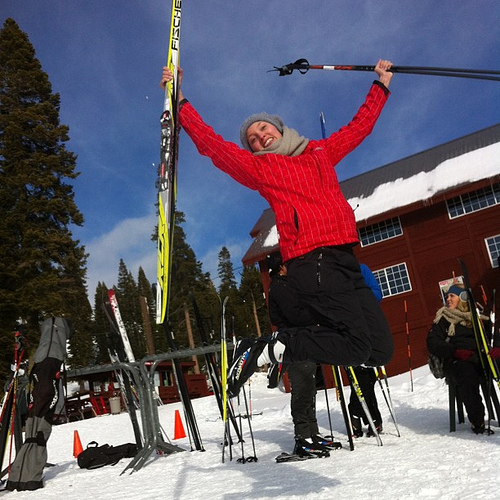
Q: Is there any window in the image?
A: Yes, there is a window.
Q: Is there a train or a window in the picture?
A: Yes, there is a window.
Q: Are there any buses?
A: No, there are no buses.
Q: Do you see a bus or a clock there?
A: No, there are no buses or clocks.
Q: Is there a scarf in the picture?
A: Yes, there is a scarf.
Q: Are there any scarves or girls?
A: Yes, there is a scarf.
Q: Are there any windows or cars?
A: Yes, there is a window.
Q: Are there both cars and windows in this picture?
A: No, there is a window but no cars.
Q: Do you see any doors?
A: No, there are no doors.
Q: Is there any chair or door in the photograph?
A: No, there are no doors or chairs.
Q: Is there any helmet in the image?
A: No, there are no helmets.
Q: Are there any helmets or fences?
A: No, there are no helmets or fences.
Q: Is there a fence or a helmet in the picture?
A: No, there are no helmets or fences.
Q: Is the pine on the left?
A: Yes, the pine is on the left of the image.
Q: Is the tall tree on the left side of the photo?
A: Yes, the pine is on the left of the image.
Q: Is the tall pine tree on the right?
A: No, the pine tree is on the left of the image.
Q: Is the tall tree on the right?
A: No, the pine tree is on the left of the image.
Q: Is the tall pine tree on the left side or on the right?
A: The pine is on the left of the image.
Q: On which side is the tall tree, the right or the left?
A: The pine is on the left of the image.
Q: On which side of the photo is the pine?
A: The pine is on the left of the image.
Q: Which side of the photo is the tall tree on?
A: The pine is on the left of the image.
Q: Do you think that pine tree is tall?
A: Yes, the pine tree is tall.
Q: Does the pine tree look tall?
A: Yes, the pine tree is tall.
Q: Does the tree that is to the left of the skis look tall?
A: Yes, the pine tree is tall.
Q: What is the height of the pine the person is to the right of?
A: The pine is tall.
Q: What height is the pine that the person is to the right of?
A: The pine is tall.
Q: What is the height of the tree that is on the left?
A: The pine is tall.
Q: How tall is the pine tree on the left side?
A: The pine tree is tall.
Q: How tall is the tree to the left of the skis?
A: The pine tree is tall.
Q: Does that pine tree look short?
A: No, the pine tree is tall.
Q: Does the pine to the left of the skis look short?
A: No, the pine is tall.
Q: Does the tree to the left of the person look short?
A: No, the pine is tall.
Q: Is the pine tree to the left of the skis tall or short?
A: The pine tree is tall.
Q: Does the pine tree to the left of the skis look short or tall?
A: The pine tree is tall.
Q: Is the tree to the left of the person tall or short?
A: The pine tree is tall.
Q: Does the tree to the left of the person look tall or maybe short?
A: The pine tree is tall.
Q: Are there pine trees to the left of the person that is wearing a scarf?
A: Yes, there is a pine tree to the left of the person.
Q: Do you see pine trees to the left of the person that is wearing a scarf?
A: Yes, there is a pine tree to the left of the person.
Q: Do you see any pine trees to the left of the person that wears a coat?
A: Yes, there is a pine tree to the left of the person.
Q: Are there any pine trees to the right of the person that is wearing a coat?
A: No, the pine tree is to the left of the person.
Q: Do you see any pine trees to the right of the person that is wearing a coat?
A: No, the pine tree is to the left of the person.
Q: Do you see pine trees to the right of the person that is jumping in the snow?
A: No, the pine tree is to the left of the person.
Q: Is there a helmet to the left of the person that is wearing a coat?
A: No, there is a pine tree to the left of the person.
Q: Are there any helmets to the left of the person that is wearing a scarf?
A: No, there is a pine tree to the left of the person.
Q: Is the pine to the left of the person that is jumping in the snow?
A: Yes, the pine is to the left of the person.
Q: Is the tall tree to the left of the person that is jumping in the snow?
A: Yes, the pine is to the left of the person.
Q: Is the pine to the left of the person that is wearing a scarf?
A: Yes, the pine is to the left of the person.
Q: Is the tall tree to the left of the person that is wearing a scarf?
A: Yes, the pine is to the left of the person.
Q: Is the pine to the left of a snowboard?
A: No, the pine is to the left of the person.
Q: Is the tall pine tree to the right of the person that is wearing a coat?
A: No, the pine tree is to the left of the person.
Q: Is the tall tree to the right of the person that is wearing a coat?
A: No, the pine tree is to the left of the person.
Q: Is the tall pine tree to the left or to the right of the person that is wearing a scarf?
A: The pine tree is to the left of the person.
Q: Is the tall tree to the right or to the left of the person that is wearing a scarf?
A: The pine tree is to the left of the person.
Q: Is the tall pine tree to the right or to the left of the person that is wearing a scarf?
A: The pine tree is to the left of the person.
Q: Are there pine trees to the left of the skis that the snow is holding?
A: Yes, there is a pine tree to the left of the skis.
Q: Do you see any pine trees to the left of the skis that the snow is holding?
A: Yes, there is a pine tree to the left of the skis.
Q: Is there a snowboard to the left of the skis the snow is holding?
A: No, there is a pine tree to the left of the skis.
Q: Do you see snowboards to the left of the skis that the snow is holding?
A: No, there is a pine tree to the left of the skis.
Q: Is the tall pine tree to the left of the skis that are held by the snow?
A: Yes, the pine tree is to the left of the skis.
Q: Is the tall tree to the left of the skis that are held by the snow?
A: Yes, the pine tree is to the left of the skis.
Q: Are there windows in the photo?
A: Yes, there is a window.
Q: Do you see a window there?
A: Yes, there is a window.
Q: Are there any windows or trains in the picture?
A: Yes, there is a window.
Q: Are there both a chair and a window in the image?
A: No, there is a window but no chairs.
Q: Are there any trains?
A: No, there are no trains.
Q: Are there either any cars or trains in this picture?
A: No, there are no trains or cars.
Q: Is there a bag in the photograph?
A: Yes, there is a bag.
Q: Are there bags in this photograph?
A: Yes, there is a bag.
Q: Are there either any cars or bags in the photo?
A: Yes, there is a bag.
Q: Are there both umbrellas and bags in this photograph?
A: No, there is a bag but no umbrellas.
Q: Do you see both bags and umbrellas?
A: No, there is a bag but no umbrellas.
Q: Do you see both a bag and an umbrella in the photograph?
A: No, there is a bag but no umbrellas.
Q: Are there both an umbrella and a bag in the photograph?
A: No, there is a bag but no umbrellas.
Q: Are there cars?
A: No, there are no cars.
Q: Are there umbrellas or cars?
A: No, there are no cars or umbrellas.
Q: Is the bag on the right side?
A: No, the bag is on the left of the image.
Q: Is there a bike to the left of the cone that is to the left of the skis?
A: No, there is a bag to the left of the safety cone.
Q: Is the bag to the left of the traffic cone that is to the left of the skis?
A: Yes, the bag is to the left of the traffic cone.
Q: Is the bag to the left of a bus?
A: No, the bag is to the left of the traffic cone.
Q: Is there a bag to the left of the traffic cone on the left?
A: Yes, there is a bag to the left of the safety cone.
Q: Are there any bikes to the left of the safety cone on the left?
A: No, there is a bag to the left of the safety cone.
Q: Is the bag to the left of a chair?
A: No, the bag is to the left of the cone.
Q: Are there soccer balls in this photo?
A: No, there are no soccer balls.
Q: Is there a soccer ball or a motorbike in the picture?
A: No, there are no soccer balls or motorcycles.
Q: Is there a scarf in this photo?
A: Yes, there is a scarf.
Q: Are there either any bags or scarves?
A: Yes, there is a scarf.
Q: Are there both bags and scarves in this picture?
A: Yes, there are both a scarf and a bag.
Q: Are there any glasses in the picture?
A: No, there are no glasses.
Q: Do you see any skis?
A: Yes, there are skis.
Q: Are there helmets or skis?
A: Yes, there are skis.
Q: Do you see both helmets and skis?
A: No, there are skis but no helmets.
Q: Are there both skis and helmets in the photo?
A: No, there are skis but no helmets.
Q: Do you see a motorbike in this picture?
A: No, there are no motorcycles.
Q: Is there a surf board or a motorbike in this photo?
A: No, there are no motorcycles or surfboards.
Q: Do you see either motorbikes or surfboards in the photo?
A: No, there are no motorbikes or surfboards.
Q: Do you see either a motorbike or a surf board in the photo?
A: No, there are no motorcycles or surfboards.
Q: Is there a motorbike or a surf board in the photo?
A: No, there are no motorcycles or surfboards.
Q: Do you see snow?
A: Yes, there is snow.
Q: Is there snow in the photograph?
A: Yes, there is snow.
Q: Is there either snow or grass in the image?
A: Yes, there is snow.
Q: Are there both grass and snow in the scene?
A: No, there is snow but no grass.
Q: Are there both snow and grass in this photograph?
A: No, there is snow but no grass.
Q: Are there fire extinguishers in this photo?
A: No, there are no fire extinguishers.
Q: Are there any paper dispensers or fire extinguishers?
A: No, there are no fire extinguishers or paper dispensers.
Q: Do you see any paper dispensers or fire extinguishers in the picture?
A: No, there are no fire extinguishers or paper dispensers.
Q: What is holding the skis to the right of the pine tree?
A: The snow is holding the skis.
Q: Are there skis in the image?
A: Yes, there are skis.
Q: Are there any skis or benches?
A: Yes, there are skis.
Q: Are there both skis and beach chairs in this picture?
A: No, there are skis but no beach chairs.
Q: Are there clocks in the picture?
A: No, there are no clocks.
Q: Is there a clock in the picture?
A: No, there are no clocks.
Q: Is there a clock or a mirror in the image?
A: No, there are no clocks or mirrors.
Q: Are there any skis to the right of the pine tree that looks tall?
A: Yes, there are skis to the right of the pine tree.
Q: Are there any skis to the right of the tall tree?
A: Yes, there are skis to the right of the pine tree.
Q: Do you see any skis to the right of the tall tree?
A: Yes, there are skis to the right of the pine tree.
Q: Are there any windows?
A: Yes, there is a window.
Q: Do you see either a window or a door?
A: Yes, there is a window.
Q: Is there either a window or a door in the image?
A: Yes, there is a window.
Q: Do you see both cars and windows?
A: No, there is a window but no cars.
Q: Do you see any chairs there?
A: No, there are no chairs.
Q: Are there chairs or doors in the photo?
A: No, there are no chairs or doors.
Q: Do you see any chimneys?
A: No, there are no chimneys.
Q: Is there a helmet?
A: No, there are no helmets.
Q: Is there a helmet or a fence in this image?
A: No, there are no helmets or fences.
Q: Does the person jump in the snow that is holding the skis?
A: Yes, the person jumps in the snow.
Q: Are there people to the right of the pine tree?
A: Yes, there is a person to the right of the pine tree.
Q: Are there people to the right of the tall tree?
A: Yes, there is a person to the right of the pine tree.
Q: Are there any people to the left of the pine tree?
A: No, the person is to the right of the pine tree.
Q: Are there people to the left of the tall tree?
A: No, the person is to the right of the pine tree.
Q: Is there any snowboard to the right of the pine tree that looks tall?
A: No, there is a person to the right of the pine tree.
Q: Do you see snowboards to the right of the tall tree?
A: No, there is a person to the right of the pine tree.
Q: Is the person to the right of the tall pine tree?
A: Yes, the person is to the right of the pine tree.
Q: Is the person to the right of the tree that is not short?
A: Yes, the person is to the right of the pine tree.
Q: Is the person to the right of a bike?
A: No, the person is to the right of the pine tree.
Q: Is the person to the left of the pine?
A: No, the person is to the right of the pine.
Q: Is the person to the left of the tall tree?
A: No, the person is to the right of the pine.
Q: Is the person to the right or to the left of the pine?
A: The person is to the right of the pine.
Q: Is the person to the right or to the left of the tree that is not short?
A: The person is to the right of the pine.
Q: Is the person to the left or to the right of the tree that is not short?
A: The person is to the right of the pine.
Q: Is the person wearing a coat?
A: Yes, the person is wearing a coat.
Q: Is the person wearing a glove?
A: No, the person is wearing a coat.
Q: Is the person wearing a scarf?
A: Yes, the person is wearing a scarf.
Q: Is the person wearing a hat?
A: No, the person is wearing a scarf.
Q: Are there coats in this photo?
A: Yes, there is a coat.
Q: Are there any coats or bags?
A: Yes, there is a coat.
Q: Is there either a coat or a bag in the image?
A: Yes, there is a coat.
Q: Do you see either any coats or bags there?
A: Yes, there is a coat.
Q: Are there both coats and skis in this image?
A: Yes, there are both a coat and skis.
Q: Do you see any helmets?
A: No, there are no helmets.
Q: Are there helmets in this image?
A: No, there are no helmets.